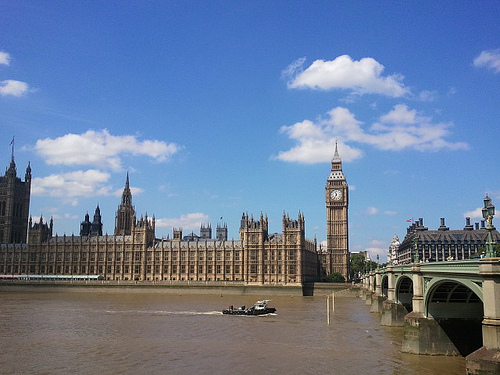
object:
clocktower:
[325, 137, 349, 281]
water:
[1, 291, 467, 374]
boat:
[222, 298, 277, 316]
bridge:
[359, 192, 500, 374]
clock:
[329, 190, 343, 201]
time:
[331, 189, 342, 200]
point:
[332, 137, 341, 159]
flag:
[9, 135, 14, 145]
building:
[0, 158, 33, 245]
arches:
[420, 278, 483, 320]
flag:
[219, 216, 223, 220]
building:
[216, 222, 227, 242]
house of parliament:
[2, 159, 317, 282]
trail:
[107, 310, 223, 315]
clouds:
[278, 53, 416, 101]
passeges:
[421, 277, 484, 362]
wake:
[105, 309, 224, 317]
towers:
[114, 170, 137, 236]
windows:
[2, 254, 296, 282]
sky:
[1, 1, 499, 264]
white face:
[329, 190, 343, 203]